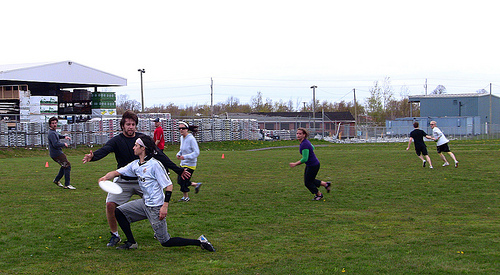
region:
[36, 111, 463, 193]
People playing frisbee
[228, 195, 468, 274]
green grass of the field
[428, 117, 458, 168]
Man wearing white in background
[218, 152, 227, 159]
Small orange cone to mark boundary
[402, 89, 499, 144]
Blue one story house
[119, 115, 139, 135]
Man has a beard and mustache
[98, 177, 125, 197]
Medium sized white frisbee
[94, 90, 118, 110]
Green crates behind man's head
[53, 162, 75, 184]
Man wearing high black socks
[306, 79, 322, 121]
Tall pole in background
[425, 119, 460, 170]
man in white shirt and black shorts running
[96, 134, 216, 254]
man kneeling and throwing frisbee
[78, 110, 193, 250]
man in blue sweat shirt blocking other player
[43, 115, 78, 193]
man in grey sweat shirt stopping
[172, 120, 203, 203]
woman with sunglasses running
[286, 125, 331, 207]
woman in blue and green shirt charging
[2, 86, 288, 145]
retail storage lot behind players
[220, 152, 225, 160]
orange cone on field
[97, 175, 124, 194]
white frisbee in man's hand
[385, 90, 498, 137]
blue metal building behind fence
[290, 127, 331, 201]
Young person wearing purple shirt with green arms.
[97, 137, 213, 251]
Young man in white shirt, on one knee, trying to aim and toss frisbee.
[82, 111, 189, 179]
Young man wearing black sweater trying to block throw of Frisbee.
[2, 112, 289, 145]
Bags of soil, cement, or mulch piled against chain link fence.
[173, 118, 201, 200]
Young woman in grey sweatshirt hoping to block frisbee.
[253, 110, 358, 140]
Brick utility building with many garages or car wash.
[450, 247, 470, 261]
Dandelions in grass.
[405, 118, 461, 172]
Two persons getting exercise.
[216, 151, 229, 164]
Orange delineation cone in grass.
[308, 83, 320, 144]
Light on pole for evening illumination.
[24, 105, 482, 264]
group of people on a field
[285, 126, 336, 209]
young woman running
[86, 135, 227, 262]
young woman with a white frisbee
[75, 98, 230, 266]
man trying to block woman with frisbee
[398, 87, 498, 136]
gray building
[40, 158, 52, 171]
tiny orange cone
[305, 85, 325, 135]
tall and skinny pole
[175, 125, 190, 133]
dark sunglasses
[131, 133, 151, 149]
thick white headband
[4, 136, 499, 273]
large green field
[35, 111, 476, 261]
people playing a game with a Frisbee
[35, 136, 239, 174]
small orange cones on the ground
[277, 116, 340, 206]
person running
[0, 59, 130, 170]
large open building near field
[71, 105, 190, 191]
man wearing a long sleeved black shirt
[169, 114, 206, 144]
woman's dark hair flying behind her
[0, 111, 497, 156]
long chain-link fence near grass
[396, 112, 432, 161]
person dressed in black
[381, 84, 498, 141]
large blue building behind fence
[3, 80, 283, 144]
stacked items near building